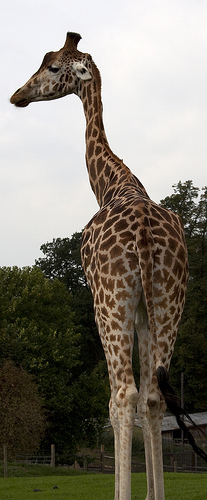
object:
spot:
[93, 144, 100, 154]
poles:
[1, 443, 55, 475]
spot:
[87, 158, 97, 181]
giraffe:
[8, 31, 190, 499]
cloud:
[95, 0, 205, 82]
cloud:
[137, 97, 202, 149]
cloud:
[156, 151, 205, 169]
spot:
[86, 119, 96, 136]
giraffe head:
[8, 31, 90, 108]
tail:
[135, 226, 207, 474]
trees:
[157, 177, 206, 476]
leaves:
[191, 317, 201, 336]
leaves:
[17, 276, 32, 286]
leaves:
[57, 252, 72, 280]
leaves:
[179, 185, 196, 195]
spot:
[94, 156, 106, 174]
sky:
[0, 1, 207, 274]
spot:
[82, 105, 96, 114]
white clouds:
[0, 160, 13, 206]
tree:
[1, 357, 44, 467]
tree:
[33, 232, 99, 361]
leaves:
[3, 265, 79, 364]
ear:
[74, 63, 92, 81]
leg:
[105, 307, 138, 499]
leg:
[108, 401, 121, 499]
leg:
[137, 323, 155, 499]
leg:
[147, 304, 177, 499]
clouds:
[112, 95, 126, 111]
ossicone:
[64, 31, 82, 51]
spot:
[51, 79, 56, 85]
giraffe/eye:
[48, 64, 61, 73]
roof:
[102, 411, 207, 442]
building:
[77, 393, 207, 473]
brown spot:
[127, 213, 135, 221]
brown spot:
[69, 76, 73, 80]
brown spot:
[94, 95, 98, 113]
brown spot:
[82, 100, 87, 109]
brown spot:
[92, 127, 97, 134]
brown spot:
[95, 146, 102, 155]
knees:
[109, 379, 165, 434]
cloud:
[62, 156, 89, 173]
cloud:
[21, 182, 77, 209]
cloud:
[10, 207, 26, 237]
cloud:
[8, 146, 55, 183]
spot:
[151, 266, 176, 293]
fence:
[0, 437, 114, 474]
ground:
[0, 473, 207, 499]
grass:
[0, 465, 207, 500]